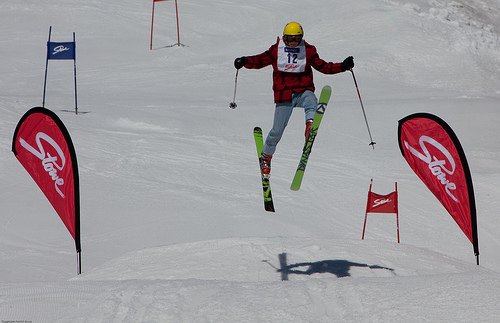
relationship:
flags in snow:
[10, 96, 108, 288] [6, 4, 496, 320]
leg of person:
[260, 105, 292, 161] [224, 15, 361, 159]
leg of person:
[293, 84, 323, 130] [232, 23, 352, 177]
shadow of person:
[274, 235, 388, 295] [232, 23, 352, 177]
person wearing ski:
[232, 23, 352, 177] [246, 124, 281, 216]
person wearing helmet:
[232, 23, 352, 177] [273, 16, 307, 45]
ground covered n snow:
[14, 15, 486, 313] [127, 166, 191, 240]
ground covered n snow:
[14, 15, 486, 313] [127, 139, 215, 236]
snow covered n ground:
[0, 0, 499, 323] [14, 15, 486, 313]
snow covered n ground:
[102, 192, 234, 292] [14, 15, 486, 313]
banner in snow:
[15, 95, 109, 284] [88, 93, 199, 244]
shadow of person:
[259, 252, 397, 282] [232, 20, 355, 175]